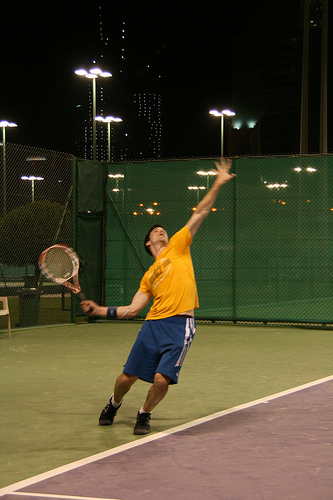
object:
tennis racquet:
[29, 241, 103, 327]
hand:
[211, 157, 237, 184]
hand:
[80, 299, 99, 317]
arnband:
[106, 307, 118, 319]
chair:
[0, 291, 13, 340]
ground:
[208, 433, 259, 500]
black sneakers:
[99, 393, 152, 435]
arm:
[181, 182, 220, 253]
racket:
[38, 243, 93, 317]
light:
[74, 68, 113, 80]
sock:
[111, 395, 123, 408]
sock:
[139, 406, 152, 414]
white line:
[17, 363, 317, 492]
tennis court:
[4, 320, 322, 498]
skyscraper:
[74, 3, 162, 161]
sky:
[1, 0, 332, 157]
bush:
[0, 198, 91, 259]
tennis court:
[1, 308, 332, 499]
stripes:
[175, 317, 197, 377]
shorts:
[123, 315, 198, 385]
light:
[94, 115, 124, 122]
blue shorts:
[122, 315, 196, 386]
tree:
[1, 202, 73, 280]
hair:
[144, 224, 165, 256]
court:
[5, 310, 331, 498]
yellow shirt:
[137, 223, 199, 321]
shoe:
[99, 392, 124, 425]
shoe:
[134, 410, 152, 435]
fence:
[0, 141, 333, 327]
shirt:
[139, 224, 200, 320]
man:
[80, 156, 236, 435]